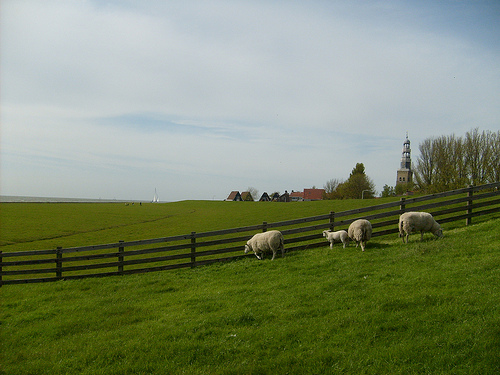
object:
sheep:
[245, 230, 284, 265]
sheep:
[319, 230, 345, 248]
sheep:
[349, 221, 376, 254]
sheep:
[396, 212, 443, 245]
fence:
[0, 182, 499, 289]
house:
[225, 192, 242, 207]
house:
[241, 192, 255, 203]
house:
[260, 192, 274, 202]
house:
[269, 193, 281, 202]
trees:
[411, 142, 438, 195]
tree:
[434, 138, 450, 195]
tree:
[452, 139, 466, 186]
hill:
[0, 187, 499, 374]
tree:
[469, 129, 486, 181]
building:
[394, 133, 413, 197]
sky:
[0, 0, 488, 201]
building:
[302, 188, 328, 206]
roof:
[303, 189, 330, 201]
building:
[289, 191, 305, 204]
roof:
[291, 192, 305, 197]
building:
[271, 192, 284, 204]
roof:
[261, 192, 269, 200]